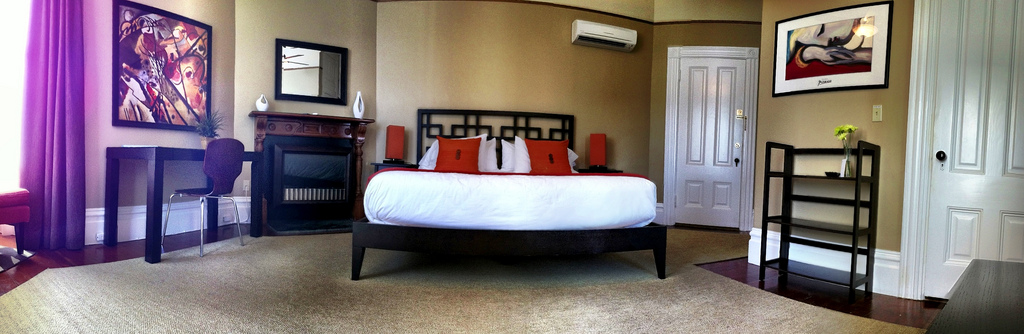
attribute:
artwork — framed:
[772, 4, 893, 93]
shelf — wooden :
[757, 140, 878, 296]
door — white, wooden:
[916, 5, 1022, 304]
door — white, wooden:
[664, 47, 745, 225]